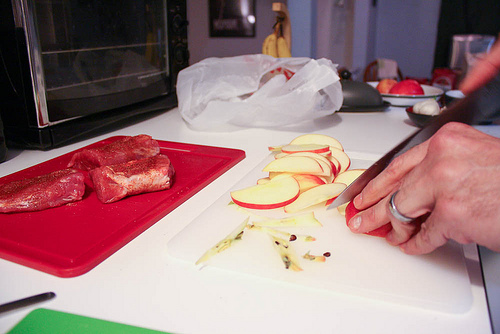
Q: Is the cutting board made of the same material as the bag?
A: Yes, both the cutting board and the bag are made of plastic.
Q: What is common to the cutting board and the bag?
A: The material, both the cutting board and the bag are plastic.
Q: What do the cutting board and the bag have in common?
A: The material, both the cutting board and the bag are plastic.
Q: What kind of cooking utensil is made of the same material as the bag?
A: The cutting board is made of the same material as the bag.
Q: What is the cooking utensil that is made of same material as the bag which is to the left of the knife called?
A: The cooking utensil is a cutting board.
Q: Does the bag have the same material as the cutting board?
A: Yes, both the bag and the cutting board are made of plastic.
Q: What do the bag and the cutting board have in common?
A: The material, both the bag and the cutting board are plastic.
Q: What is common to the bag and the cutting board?
A: The material, both the bag and the cutting board are plastic.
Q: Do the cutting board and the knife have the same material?
A: No, the cutting board is made of plastic and the knife is made of metal.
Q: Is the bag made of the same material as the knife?
A: No, the bag is made of plastic and the knife is made of metal.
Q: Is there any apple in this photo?
A: Yes, there is an apple.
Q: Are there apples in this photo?
A: Yes, there is an apple.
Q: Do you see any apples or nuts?
A: Yes, there is an apple.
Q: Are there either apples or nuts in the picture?
A: Yes, there is an apple.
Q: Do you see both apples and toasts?
A: No, there is an apple but no toasts.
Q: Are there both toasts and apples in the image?
A: No, there is an apple but no toasts.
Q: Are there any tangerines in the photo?
A: No, there are no tangerines.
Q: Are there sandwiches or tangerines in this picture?
A: No, there are no tangerines or sandwiches.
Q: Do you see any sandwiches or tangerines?
A: No, there are no tangerines or sandwiches.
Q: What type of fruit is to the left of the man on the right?
A: The fruit is an apple.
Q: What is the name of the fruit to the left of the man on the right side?
A: The fruit is an apple.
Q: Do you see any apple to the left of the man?
A: Yes, there is an apple to the left of the man.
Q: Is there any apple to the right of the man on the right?
A: No, the apple is to the left of the man.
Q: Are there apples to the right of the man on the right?
A: No, the apple is to the left of the man.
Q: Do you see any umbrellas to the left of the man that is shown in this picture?
A: No, there is an apple to the left of the man.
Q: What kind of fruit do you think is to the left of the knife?
A: The fruit is an apple.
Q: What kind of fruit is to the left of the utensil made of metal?
A: The fruit is an apple.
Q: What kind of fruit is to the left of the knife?
A: The fruit is an apple.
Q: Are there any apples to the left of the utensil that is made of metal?
A: Yes, there is an apple to the left of the knife.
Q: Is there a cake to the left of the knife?
A: No, there is an apple to the left of the knife.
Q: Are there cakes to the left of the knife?
A: No, there is an apple to the left of the knife.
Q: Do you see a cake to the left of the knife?
A: No, there is an apple to the left of the knife.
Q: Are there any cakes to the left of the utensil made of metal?
A: No, there is an apple to the left of the knife.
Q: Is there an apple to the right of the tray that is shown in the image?
A: Yes, there is an apple to the right of the tray.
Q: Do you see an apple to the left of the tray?
A: No, the apple is to the right of the tray.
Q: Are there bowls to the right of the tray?
A: No, there is an apple to the right of the tray.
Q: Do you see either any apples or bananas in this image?
A: Yes, there is an apple.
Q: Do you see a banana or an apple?
A: Yes, there is an apple.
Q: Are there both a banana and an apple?
A: Yes, there are both an apple and a banana.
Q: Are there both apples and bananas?
A: Yes, there are both an apple and bananas.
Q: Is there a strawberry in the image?
A: No, there are no strawberries.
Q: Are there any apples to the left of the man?
A: Yes, there is an apple to the left of the man.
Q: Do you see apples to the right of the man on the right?
A: No, the apple is to the left of the man.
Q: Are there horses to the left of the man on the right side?
A: No, there is an apple to the left of the man.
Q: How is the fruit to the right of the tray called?
A: The fruit is an apple.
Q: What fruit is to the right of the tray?
A: The fruit is an apple.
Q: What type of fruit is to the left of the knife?
A: The fruit is an apple.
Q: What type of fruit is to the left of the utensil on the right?
A: The fruit is an apple.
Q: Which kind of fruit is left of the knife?
A: The fruit is an apple.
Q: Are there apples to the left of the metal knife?
A: Yes, there is an apple to the left of the knife.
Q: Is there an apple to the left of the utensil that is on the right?
A: Yes, there is an apple to the left of the knife.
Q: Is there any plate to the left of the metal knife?
A: No, there is an apple to the left of the knife.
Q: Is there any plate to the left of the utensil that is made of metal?
A: No, there is an apple to the left of the knife.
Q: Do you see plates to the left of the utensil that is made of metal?
A: No, there is an apple to the left of the knife.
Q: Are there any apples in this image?
A: Yes, there is an apple.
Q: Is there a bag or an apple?
A: Yes, there is an apple.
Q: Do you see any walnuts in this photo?
A: No, there are no walnuts.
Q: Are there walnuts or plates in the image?
A: No, there are no walnuts or plates.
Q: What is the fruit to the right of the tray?
A: The fruit is an apple.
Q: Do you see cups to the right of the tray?
A: No, there is an apple to the right of the tray.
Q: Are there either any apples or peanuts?
A: Yes, there is an apple.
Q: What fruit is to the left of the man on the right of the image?
A: The fruit is an apple.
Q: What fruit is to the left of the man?
A: The fruit is an apple.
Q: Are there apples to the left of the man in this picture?
A: Yes, there is an apple to the left of the man.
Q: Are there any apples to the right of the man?
A: No, the apple is to the left of the man.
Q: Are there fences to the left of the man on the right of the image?
A: No, there is an apple to the left of the man.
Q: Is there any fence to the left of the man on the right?
A: No, there is an apple to the left of the man.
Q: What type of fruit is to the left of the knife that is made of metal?
A: The fruit is an apple.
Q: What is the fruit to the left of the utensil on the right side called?
A: The fruit is an apple.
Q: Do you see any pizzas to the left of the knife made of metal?
A: No, there is an apple to the left of the knife.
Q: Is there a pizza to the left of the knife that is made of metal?
A: No, there is an apple to the left of the knife.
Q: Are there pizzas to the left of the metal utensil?
A: No, there is an apple to the left of the knife.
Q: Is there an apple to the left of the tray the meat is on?
A: No, the apple is to the right of the tray.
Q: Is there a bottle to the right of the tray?
A: No, there is an apple to the right of the tray.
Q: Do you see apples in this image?
A: Yes, there is an apple.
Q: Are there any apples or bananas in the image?
A: Yes, there is an apple.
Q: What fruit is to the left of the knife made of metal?
A: The fruit is an apple.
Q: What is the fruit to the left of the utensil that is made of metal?
A: The fruit is an apple.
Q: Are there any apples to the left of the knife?
A: Yes, there is an apple to the left of the knife.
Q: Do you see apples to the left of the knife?
A: Yes, there is an apple to the left of the knife.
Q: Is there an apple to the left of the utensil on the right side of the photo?
A: Yes, there is an apple to the left of the knife.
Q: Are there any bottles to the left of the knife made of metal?
A: No, there is an apple to the left of the knife.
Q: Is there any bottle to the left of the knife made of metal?
A: No, there is an apple to the left of the knife.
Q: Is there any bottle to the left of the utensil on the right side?
A: No, there is an apple to the left of the knife.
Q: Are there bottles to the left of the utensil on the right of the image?
A: No, there is an apple to the left of the knife.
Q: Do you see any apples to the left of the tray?
A: No, the apple is to the right of the tray.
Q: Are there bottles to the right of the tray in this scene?
A: No, there is an apple to the right of the tray.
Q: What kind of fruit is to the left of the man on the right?
A: The fruit is an apple.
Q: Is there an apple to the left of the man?
A: Yes, there is an apple to the left of the man.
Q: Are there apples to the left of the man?
A: Yes, there is an apple to the left of the man.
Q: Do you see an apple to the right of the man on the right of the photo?
A: No, the apple is to the left of the man.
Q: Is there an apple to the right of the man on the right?
A: No, the apple is to the left of the man.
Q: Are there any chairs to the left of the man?
A: No, there is an apple to the left of the man.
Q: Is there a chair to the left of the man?
A: No, there is an apple to the left of the man.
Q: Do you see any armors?
A: No, there are no armors.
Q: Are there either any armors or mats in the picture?
A: No, there are no armors or mats.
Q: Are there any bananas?
A: Yes, there is a banana.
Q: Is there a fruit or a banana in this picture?
A: Yes, there is a banana.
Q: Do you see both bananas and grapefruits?
A: No, there is a banana but no grapefruits.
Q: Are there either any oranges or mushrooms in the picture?
A: No, there are no oranges or mushrooms.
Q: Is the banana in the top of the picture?
A: Yes, the banana is in the top of the image.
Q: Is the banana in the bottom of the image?
A: No, the banana is in the top of the image.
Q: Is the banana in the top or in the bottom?
A: The banana is in the top of the image.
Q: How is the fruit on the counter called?
A: The fruit is a banana.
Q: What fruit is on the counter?
A: The fruit is a banana.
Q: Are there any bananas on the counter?
A: Yes, there is a banana on the counter.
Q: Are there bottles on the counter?
A: No, there is a banana on the counter.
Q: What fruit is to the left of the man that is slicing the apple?
A: The fruit is a banana.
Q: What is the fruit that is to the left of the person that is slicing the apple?
A: The fruit is a banana.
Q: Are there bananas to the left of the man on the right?
A: Yes, there is a banana to the left of the man.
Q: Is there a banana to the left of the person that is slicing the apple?
A: Yes, there is a banana to the left of the man.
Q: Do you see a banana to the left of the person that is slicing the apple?
A: Yes, there is a banana to the left of the man.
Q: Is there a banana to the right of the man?
A: No, the banana is to the left of the man.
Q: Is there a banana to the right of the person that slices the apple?
A: No, the banana is to the left of the man.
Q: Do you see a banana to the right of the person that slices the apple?
A: No, the banana is to the left of the man.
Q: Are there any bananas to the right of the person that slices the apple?
A: No, the banana is to the left of the man.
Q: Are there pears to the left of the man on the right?
A: No, there is a banana to the left of the man.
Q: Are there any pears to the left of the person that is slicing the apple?
A: No, there is a banana to the left of the man.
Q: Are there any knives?
A: Yes, there is a knife.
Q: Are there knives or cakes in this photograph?
A: Yes, there is a knife.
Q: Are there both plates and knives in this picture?
A: No, there is a knife but no plates.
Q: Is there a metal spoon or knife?
A: Yes, there is a metal knife.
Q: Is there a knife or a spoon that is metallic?
A: Yes, the knife is metallic.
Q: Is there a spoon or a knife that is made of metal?
A: Yes, the knife is made of metal.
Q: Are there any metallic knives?
A: Yes, there is a metal knife.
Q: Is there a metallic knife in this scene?
A: Yes, there is a metal knife.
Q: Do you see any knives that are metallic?
A: Yes, there is a knife that is metallic.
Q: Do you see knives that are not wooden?
A: Yes, there is a metallic knife.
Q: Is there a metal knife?
A: Yes, there is a knife that is made of metal.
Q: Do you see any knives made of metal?
A: Yes, there is a knife that is made of metal.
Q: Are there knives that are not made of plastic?
A: Yes, there is a knife that is made of metal.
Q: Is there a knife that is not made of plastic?
A: Yes, there is a knife that is made of metal.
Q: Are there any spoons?
A: No, there are no spoons.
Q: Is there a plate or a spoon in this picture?
A: No, there are no spoons or plates.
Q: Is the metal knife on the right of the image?
A: Yes, the knife is on the right of the image.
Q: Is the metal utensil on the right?
A: Yes, the knife is on the right of the image.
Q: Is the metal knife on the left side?
A: No, the knife is on the right of the image.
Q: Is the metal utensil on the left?
A: No, the knife is on the right of the image.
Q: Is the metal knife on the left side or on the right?
A: The knife is on the right of the image.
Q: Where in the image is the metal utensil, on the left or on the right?
A: The knife is on the right of the image.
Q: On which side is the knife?
A: The knife is on the right of the image.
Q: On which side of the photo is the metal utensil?
A: The knife is on the right of the image.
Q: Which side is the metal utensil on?
A: The knife is on the right of the image.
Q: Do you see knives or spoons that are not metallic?
A: No, there is a knife but it is metallic.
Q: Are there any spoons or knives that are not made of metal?
A: No, there is a knife but it is made of metal.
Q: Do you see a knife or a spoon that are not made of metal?
A: No, there is a knife but it is made of metal.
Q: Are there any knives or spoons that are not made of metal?
A: No, there is a knife but it is made of metal.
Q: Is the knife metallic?
A: Yes, the knife is metallic.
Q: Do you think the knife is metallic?
A: Yes, the knife is metallic.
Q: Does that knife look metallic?
A: Yes, the knife is metallic.